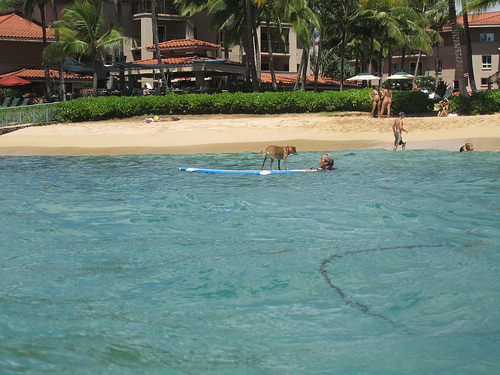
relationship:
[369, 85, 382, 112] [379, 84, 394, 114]
woman standing with woman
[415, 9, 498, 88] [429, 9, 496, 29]
house with roof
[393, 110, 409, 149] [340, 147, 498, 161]
person standing in seashore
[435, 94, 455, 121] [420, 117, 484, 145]
woman in sand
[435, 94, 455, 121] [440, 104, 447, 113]
woman wearing wetsuit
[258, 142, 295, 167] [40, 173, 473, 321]
dog paddle boarding in ocean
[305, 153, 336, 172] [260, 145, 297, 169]
vacationer has dog